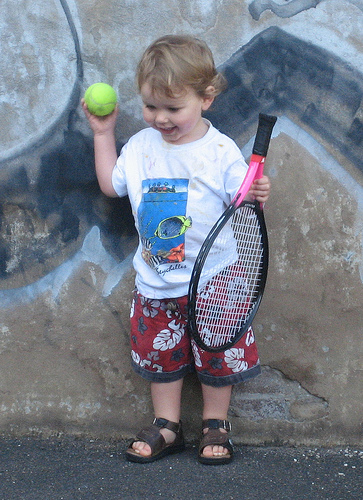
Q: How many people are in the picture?
A: One.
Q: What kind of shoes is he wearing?
A: Sandals.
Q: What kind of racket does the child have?
A: A tennis racket.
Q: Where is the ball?
A: In his hand.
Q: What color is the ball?
A: Green.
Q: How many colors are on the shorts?
A: Four.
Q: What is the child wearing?
A: Shorts and a t-shirt.